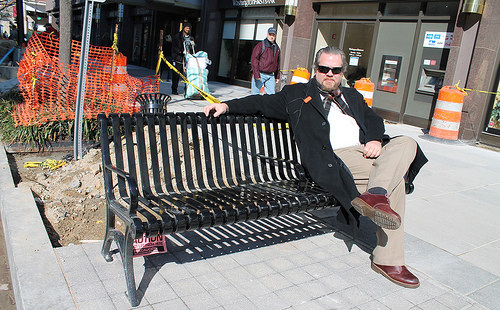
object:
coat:
[220, 76, 428, 229]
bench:
[96, 111, 363, 307]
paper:
[131, 231, 168, 257]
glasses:
[317, 66, 343, 75]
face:
[317, 53, 344, 88]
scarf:
[316, 87, 355, 118]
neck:
[320, 84, 341, 94]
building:
[10, 0, 498, 153]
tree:
[56, 0, 72, 117]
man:
[250, 27, 281, 95]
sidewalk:
[124, 62, 495, 279]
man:
[171, 26, 195, 94]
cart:
[181, 40, 213, 100]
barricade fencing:
[9, 31, 161, 126]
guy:
[203, 45, 427, 288]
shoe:
[370, 260, 419, 289]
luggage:
[183, 41, 211, 98]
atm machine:
[418, 68, 441, 91]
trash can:
[135, 92, 172, 113]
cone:
[430, 86, 465, 140]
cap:
[269, 27, 278, 34]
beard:
[317, 80, 340, 93]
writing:
[133, 234, 164, 255]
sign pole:
[71, 1, 94, 162]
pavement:
[0, 63, 495, 303]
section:
[13, 108, 271, 246]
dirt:
[40, 120, 246, 245]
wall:
[278, 0, 499, 150]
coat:
[251, 39, 282, 79]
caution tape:
[155, 48, 220, 103]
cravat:
[317, 86, 356, 119]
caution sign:
[130, 219, 168, 258]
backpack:
[260, 39, 279, 56]